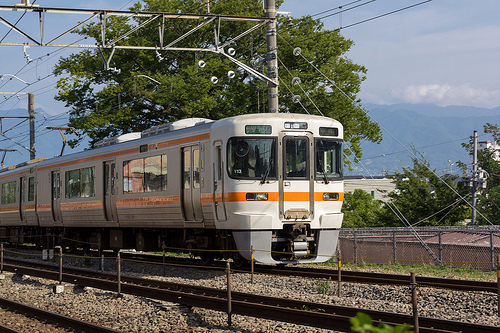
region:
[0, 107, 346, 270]
a white train with orange stripes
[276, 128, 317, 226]
a connecting door on the front of a train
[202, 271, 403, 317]
gravel along the train tracks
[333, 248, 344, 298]
a metal post with a yellow stripe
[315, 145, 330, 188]
a windshield wiper in a train window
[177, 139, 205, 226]
a door on a train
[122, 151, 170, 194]
windows on the side of a train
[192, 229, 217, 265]
the wheel of a train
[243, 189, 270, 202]
a headlight on a train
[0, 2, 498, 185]
a blue sky with clouds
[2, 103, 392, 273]
Train going down the tracks.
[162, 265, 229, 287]
Gravel in between tracks.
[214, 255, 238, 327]
Metal pole beside the tracks.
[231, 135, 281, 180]
Window of the front train car.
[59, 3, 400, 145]
Large tree in the distance.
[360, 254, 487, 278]
Grass growing beside track.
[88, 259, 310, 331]
Empty metal train tracks.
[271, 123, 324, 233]
Door on the front of the tracks.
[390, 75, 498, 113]
Clouds in the sky.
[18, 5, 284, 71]
Metal poles hanging overhead.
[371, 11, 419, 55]
white clouds in blue sky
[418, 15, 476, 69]
white clouds in blue sky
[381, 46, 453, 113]
white clouds in blue sky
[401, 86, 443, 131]
white clouds in blue sky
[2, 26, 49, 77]
white clouds in blue sky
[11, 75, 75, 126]
white clouds in blue sky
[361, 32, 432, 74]
white clouds in blue sky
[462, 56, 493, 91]
white clouds in blue sky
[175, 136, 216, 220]
the first side door of a train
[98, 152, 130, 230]
the second side door of a train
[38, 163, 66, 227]
the third side door of a train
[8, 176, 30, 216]
the fourth side door of a train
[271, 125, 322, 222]
the front door of a train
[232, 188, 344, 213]
the headlights of a train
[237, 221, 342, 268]
the bumper of a train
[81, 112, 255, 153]
the roof of a train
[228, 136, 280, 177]
glass is clear and clean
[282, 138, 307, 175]
glass is clear and clean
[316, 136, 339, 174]
glass is clear and clean